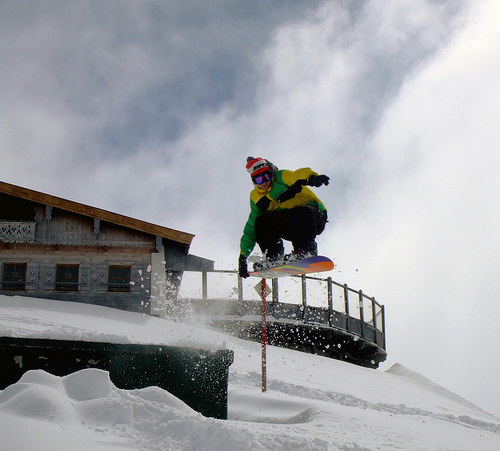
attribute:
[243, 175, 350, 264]
coat — yellow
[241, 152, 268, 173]
beanie — multi colored, winter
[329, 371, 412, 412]
snow — deep, white, fluffy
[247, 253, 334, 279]
snowboard — orange and blue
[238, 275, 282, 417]
sign — standing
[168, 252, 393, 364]
patio — large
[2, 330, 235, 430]
jump — rectangular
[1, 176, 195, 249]
roof — wooden